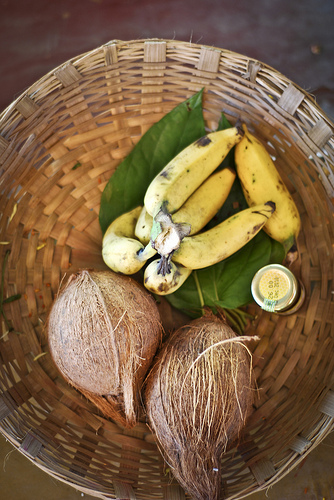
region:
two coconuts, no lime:
[37, 263, 261, 498]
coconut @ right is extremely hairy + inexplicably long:
[147, 301, 265, 498]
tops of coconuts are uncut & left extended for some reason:
[80, 363, 227, 498]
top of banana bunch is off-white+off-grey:
[148, 209, 192, 258]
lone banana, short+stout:
[233, 119, 305, 261]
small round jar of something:
[249, 264, 307, 317]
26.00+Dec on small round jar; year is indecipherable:
[262, 270, 281, 300]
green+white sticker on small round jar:
[259, 296, 278, 312]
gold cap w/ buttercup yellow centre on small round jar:
[247, 260, 297, 312]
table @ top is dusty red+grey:
[0, 0, 333, 151]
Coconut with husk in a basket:
[46, 265, 161, 415]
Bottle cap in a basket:
[251, 262, 299, 313]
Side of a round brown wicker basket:
[4, 416, 160, 497]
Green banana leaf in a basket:
[93, 83, 216, 248]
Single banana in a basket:
[227, 116, 308, 264]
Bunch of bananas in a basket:
[99, 119, 270, 293]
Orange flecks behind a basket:
[18, 281, 61, 318]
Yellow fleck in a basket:
[31, 240, 48, 251]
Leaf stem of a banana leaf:
[190, 269, 207, 307]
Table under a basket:
[6, 4, 322, 73]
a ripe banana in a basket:
[237, 119, 304, 244]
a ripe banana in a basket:
[174, 200, 276, 265]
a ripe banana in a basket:
[171, 163, 239, 233]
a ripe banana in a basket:
[142, 121, 244, 216]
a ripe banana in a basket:
[143, 257, 182, 299]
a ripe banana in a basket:
[102, 201, 147, 274]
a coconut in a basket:
[152, 309, 250, 492]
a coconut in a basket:
[44, 265, 150, 417]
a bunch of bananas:
[108, 124, 269, 290]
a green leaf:
[103, 86, 211, 250]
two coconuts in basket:
[59, 284, 246, 480]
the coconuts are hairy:
[56, 290, 260, 460]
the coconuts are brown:
[60, 293, 253, 470]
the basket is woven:
[10, 385, 155, 495]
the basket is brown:
[13, 382, 130, 495]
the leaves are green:
[192, 244, 284, 309]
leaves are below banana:
[113, 153, 279, 292]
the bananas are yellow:
[125, 153, 292, 254]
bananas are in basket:
[77, 116, 307, 306]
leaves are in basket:
[70, 99, 216, 174]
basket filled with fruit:
[0, 46, 322, 488]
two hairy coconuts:
[36, 266, 260, 455]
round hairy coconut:
[43, 267, 169, 399]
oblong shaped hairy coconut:
[148, 307, 256, 486]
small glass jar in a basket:
[250, 269, 303, 318]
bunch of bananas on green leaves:
[104, 134, 290, 281]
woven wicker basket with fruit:
[16, 55, 104, 180]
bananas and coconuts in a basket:
[38, 117, 252, 435]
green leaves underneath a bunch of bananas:
[92, 150, 154, 189]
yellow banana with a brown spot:
[137, 124, 220, 213]